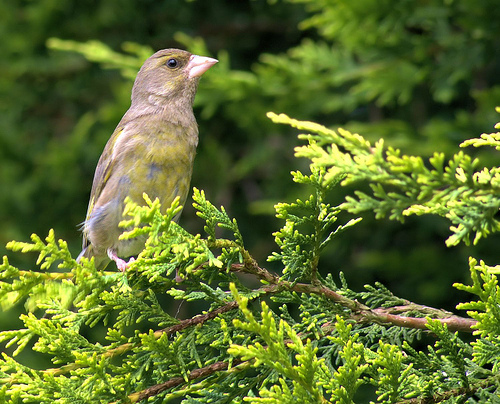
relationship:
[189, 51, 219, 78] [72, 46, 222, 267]
beak on bird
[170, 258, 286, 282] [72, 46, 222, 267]
branch underneath bird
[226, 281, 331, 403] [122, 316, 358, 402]
leaf on branch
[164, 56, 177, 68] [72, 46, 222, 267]
eye of bird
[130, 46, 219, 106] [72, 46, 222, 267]
head of bird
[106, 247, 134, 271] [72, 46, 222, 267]
foot of bird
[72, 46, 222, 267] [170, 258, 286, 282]
bird sitting on branch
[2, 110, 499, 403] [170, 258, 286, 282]
leaves under branch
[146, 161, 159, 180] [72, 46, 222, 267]
spot on bird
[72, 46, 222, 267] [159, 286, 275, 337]
bird on branch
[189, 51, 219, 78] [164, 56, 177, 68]
beak in front of eye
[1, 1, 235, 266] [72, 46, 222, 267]
tree behind bird